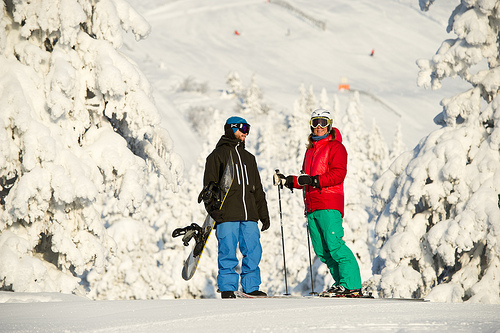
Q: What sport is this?
A: Skiing.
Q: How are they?
A: Happy.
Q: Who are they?
A: People.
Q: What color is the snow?
A: White.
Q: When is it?
A: Daytime.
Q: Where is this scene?
A: On the ski slope.